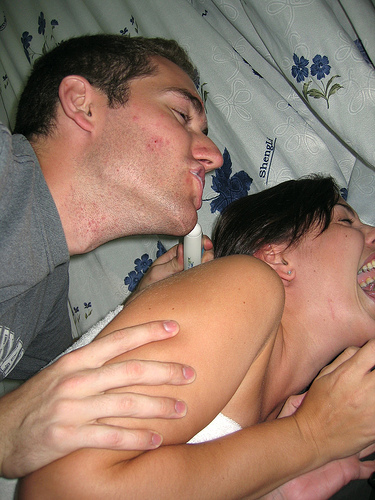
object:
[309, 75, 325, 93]
stems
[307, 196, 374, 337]
face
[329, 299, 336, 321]
scratch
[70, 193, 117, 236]
burn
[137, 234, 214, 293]
hand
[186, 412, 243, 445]
top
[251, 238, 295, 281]
ear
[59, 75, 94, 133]
ear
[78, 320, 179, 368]
finger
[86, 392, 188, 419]
finger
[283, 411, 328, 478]
wrist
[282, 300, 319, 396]
neck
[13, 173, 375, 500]
woman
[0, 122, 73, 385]
shirt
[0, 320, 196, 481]
hand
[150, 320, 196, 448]
fingernails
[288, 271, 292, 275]
earring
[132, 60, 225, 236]
face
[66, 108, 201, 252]
razor stubble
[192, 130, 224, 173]
nose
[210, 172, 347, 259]
hair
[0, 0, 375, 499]
bed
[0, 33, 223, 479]
man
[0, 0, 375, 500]
bedsheet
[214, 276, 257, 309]
freckles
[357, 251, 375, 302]
mouth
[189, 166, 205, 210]
mouth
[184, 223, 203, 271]
toothbrush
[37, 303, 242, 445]
towel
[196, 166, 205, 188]
foam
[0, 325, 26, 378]
logo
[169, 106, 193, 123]
eye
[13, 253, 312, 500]
arm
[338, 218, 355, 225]
eye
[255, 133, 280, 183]
words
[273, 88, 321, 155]
design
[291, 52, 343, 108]
design